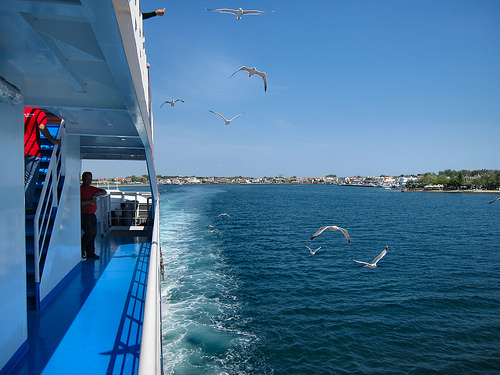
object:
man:
[21, 103, 56, 212]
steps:
[23, 142, 60, 154]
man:
[75, 169, 106, 263]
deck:
[6, 226, 153, 369]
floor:
[60, 244, 152, 371]